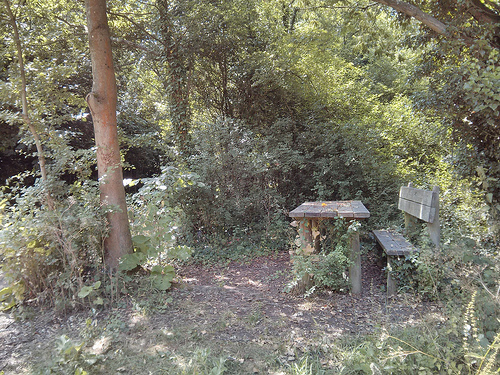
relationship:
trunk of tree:
[93, 184, 146, 282] [72, 6, 152, 281]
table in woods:
[284, 180, 373, 299] [64, 31, 477, 316]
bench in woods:
[378, 166, 444, 291] [64, 31, 477, 316]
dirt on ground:
[214, 275, 252, 301] [65, 283, 413, 365]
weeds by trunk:
[136, 197, 193, 283] [93, 184, 146, 282]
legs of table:
[295, 226, 368, 296] [284, 180, 373, 299]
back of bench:
[394, 185, 447, 219] [378, 166, 444, 291]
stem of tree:
[84, 10, 131, 76] [72, 6, 152, 281]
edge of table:
[285, 203, 300, 227] [284, 180, 373, 299]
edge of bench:
[423, 193, 443, 221] [378, 166, 444, 291]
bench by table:
[378, 166, 444, 291] [284, 180, 373, 299]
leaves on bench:
[378, 220, 405, 251] [378, 166, 444, 291]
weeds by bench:
[136, 197, 193, 283] [378, 166, 444, 291]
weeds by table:
[136, 197, 193, 283] [284, 180, 373, 299]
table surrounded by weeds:
[284, 180, 373, 299] [136, 197, 193, 283]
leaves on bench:
[309, 55, 351, 93] [378, 166, 444, 291]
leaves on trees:
[309, 55, 351, 93] [185, 15, 414, 132]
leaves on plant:
[309, 55, 351, 93] [240, 0, 348, 132]